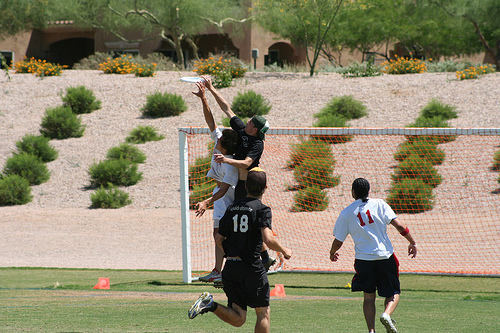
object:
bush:
[138, 87, 190, 119]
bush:
[72, 50, 182, 77]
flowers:
[97, 54, 158, 77]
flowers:
[8, 54, 68, 77]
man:
[201, 73, 278, 273]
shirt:
[332, 198, 398, 261]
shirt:
[217, 197, 272, 263]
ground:
[0, 265, 500, 333]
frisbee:
[180, 77, 205, 83]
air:
[0, 0, 500, 161]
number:
[232, 214, 249, 233]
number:
[356, 210, 375, 227]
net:
[181, 124, 500, 280]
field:
[0, 264, 500, 333]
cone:
[93, 277, 110, 289]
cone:
[270, 284, 286, 298]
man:
[186, 167, 293, 333]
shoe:
[188, 291, 215, 322]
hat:
[252, 115, 270, 140]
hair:
[352, 177, 370, 202]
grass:
[0, 267, 500, 333]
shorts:
[221, 258, 273, 311]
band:
[400, 226, 410, 236]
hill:
[0, 65, 500, 209]